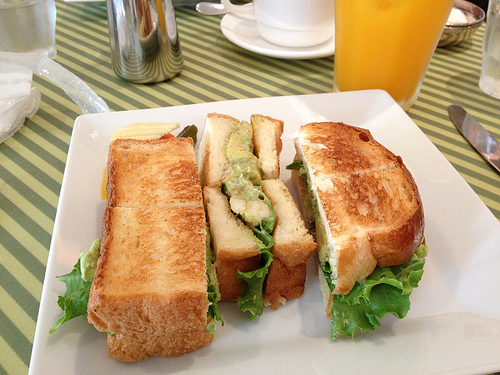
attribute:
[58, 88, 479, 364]
plate — full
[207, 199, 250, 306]
bread — white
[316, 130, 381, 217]
bread — toasted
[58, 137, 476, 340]
sandwich — nice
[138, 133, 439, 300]
sandwich — great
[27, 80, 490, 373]
plate — one, seasoned, sandwich, white, square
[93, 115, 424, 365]
portions — sandwich, flavorful, thick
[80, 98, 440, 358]
portions — delicious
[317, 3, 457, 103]
glass — one, full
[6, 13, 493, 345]
table — one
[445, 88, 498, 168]
knife — one, silver, butter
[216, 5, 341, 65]
cup — one, white, coffee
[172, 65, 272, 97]
cloth — striped, table, green, one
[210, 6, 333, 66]
plate — small, white , one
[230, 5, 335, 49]
cup — one, coffee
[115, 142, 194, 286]
toasted bread — on a plate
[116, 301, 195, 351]
sandwich — of toasted bread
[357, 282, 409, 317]
lettuce — in the sandwich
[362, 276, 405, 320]
lettuce — sticking out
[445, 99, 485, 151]
knife — on the table